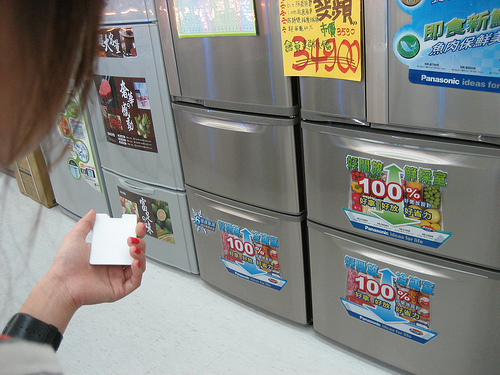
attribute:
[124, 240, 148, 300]
fingers — nail polished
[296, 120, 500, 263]
door — aluminum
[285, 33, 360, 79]
lettering — red, 34900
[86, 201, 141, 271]
phone — white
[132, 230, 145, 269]
nail polish —  red, red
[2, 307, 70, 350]
wrist band — black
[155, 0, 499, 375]
shelf — gray, aluminum, silver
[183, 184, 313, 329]
drawer — aluminum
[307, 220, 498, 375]
drawer — aluminum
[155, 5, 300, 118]
drawer — aluminum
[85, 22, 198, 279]
door — aluminum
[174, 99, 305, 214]
drawer — aluminum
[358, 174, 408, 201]
number — outlined in red, white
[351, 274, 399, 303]
number — white, outlined in red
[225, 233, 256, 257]
number — outlined in red, white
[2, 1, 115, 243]
hair — brown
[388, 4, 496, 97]
sticker — blue